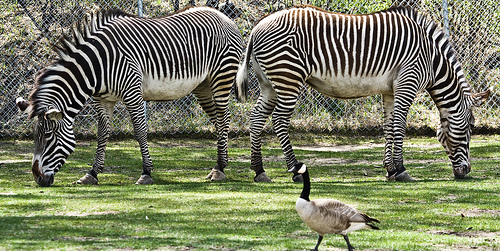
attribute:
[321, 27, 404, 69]
stripes — white, black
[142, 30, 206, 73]
stripes — white, black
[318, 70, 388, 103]
underbelly — white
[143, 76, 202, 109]
underbelly — white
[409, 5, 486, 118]
mane — striped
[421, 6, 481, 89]
stripes — black, white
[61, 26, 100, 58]
stripes — white, black